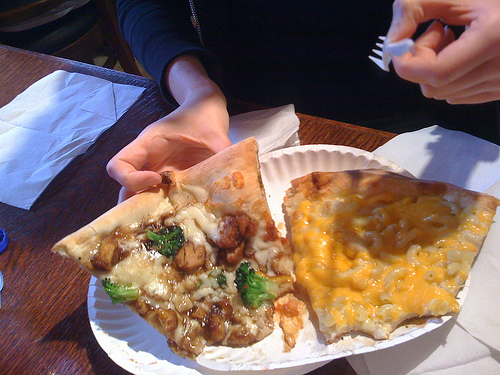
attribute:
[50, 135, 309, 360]
pizza — sliced, half-eaten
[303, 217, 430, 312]
cheese — topping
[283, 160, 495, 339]
pizza. — sliced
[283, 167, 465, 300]
pizza — sliced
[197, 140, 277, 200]
crust — pizza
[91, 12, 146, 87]
leg — brown, wooden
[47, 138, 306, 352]
pizza slice — held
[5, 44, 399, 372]
table — brown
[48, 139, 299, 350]
pizza — sliced, half eaten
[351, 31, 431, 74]
fork — plastic, white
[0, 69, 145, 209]
napkin — white, single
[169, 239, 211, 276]
mushroom — cooked, brown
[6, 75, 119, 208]
napkin — white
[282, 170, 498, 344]
pizza — sliced, half-eaten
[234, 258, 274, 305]
broccoli — piece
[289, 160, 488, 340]
pizza — sliced, eaten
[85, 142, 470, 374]
plate — white, paper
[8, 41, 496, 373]
table — wooden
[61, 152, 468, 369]
plate — white, paper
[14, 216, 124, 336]
table — wooden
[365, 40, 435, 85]
fork — white plastic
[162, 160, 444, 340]
pizza — sliced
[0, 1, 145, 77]
chair — brown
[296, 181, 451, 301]
pizza — half eaten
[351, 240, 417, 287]
macaroni — topping